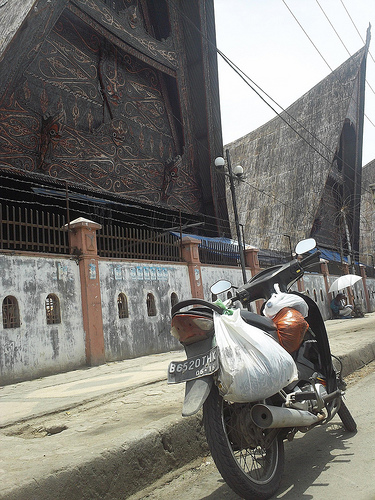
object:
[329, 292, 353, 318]
person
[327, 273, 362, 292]
umbrella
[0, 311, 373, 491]
sidewalk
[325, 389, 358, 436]
front wheel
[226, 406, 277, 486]
spokes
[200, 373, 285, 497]
wheel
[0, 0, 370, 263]
steep roofs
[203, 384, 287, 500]
back wheel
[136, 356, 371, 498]
road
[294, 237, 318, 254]
mirror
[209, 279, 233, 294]
mirror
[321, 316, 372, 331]
ground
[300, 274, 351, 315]
wall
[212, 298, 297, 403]
bag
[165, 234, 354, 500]
bike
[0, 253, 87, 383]
wall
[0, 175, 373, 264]
barbed wires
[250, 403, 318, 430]
pipe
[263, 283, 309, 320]
plastic bag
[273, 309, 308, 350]
plastic bag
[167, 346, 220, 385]
plate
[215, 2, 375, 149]
wires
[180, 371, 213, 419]
guard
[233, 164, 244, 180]
lamp